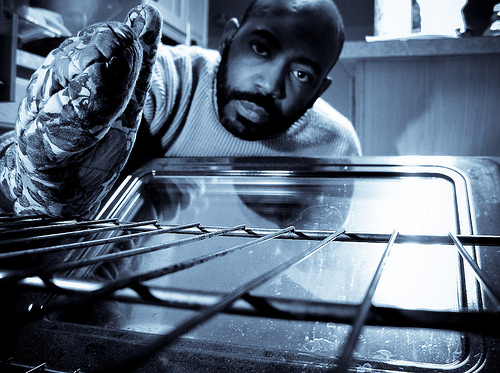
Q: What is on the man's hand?
A: Oven mitt.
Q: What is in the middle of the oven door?
A: Glass window.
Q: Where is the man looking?
A: Into oven.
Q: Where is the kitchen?
A: Behind the man.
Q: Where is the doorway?
A: Background.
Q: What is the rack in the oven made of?
A: Metal.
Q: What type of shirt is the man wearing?
A: Sweater.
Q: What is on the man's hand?
A: Mitt.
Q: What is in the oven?
A: A rack.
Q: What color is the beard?
A: Black.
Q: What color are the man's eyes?
A: Black.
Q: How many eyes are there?
A: 2.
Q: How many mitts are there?
A: One.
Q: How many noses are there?
A: One.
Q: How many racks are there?
A: One.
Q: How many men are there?
A: One.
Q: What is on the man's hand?
A: Mitt.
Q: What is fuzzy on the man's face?
A: Beard.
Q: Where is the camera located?
A: Oven.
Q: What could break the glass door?
A: Rock.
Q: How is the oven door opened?
A: Manually.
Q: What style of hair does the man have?
A: Shaved.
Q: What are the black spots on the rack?
A: Burn marks.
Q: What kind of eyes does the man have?
A: Dark.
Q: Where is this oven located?
A: Kitchen.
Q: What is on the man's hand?
A: An oven mitt.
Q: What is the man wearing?
A: Oven mitt.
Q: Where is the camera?
A: In the oven.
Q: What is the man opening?
A: Oven.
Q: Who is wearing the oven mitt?
A: The man.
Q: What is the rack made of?
A: Metal.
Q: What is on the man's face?
A: Beard.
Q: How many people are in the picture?
A: One.